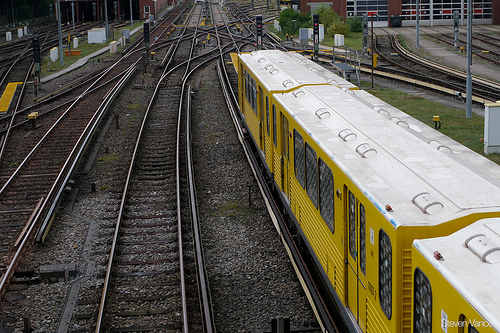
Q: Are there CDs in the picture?
A: No, there are no cds.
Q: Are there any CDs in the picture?
A: No, there are no cds.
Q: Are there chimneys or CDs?
A: No, there are no CDs or chimneys.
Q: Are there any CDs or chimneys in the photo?
A: No, there are no CDs or chimneys.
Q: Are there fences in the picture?
A: No, there are no fences.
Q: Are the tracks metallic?
A: Yes, the tracks are metallic.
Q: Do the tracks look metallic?
A: Yes, the tracks are metallic.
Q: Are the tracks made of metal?
A: Yes, the tracks are made of metal.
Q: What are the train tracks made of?
A: The train tracks are made of metal.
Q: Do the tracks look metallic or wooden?
A: The tracks are metallic.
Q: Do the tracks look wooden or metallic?
A: The tracks are metallic.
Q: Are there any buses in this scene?
A: No, there are no buses.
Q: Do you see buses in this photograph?
A: No, there are no buses.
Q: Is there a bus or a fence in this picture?
A: No, there are no buses or fences.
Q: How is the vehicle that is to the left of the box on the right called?
A: The vehicle is a car.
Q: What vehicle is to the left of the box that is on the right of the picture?
A: The vehicle is a car.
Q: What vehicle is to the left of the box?
A: The vehicle is a car.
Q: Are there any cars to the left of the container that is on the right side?
A: Yes, there is a car to the left of the box.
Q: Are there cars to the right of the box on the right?
A: No, the car is to the left of the box.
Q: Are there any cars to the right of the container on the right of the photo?
A: No, the car is to the left of the box.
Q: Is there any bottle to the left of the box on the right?
A: No, there is a car to the left of the box.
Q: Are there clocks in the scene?
A: No, there are no clocks.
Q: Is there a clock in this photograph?
A: No, there are no clocks.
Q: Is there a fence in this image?
A: No, there are no fences.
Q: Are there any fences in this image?
A: No, there are no fences.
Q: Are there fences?
A: No, there are no fences.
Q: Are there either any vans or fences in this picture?
A: No, there are no fences or vans.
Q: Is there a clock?
A: No, there are no clocks.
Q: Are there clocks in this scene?
A: No, there are no clocks.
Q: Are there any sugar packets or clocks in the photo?
A: No, there are no clocks or sugar packets.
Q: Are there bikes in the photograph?
A: No, there are no bikes.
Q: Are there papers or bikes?
A: No, there are no bikes or papers.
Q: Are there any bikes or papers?
A: No, there are no bikes or papers.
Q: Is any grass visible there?
A: Yes, there is grass.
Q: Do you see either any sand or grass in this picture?
A: Yes, there is grass.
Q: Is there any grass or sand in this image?
A: Yes, there is grass.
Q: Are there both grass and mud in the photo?
A: No, there is grass but no mud.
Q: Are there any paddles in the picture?
A: No, there are no paddles.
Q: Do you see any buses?
A: No, there are no buses.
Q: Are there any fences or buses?
A: No, there are no buses or fences.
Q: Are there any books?
A: No, there are no books.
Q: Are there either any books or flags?
A: No, there are no books or flags.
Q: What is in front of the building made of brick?
A: The shrub is in front of the building.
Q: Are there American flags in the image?
A: No, there are no American flags.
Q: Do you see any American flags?
A: No, there are no American flags.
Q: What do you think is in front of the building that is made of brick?
A: The shrub is in front of the building.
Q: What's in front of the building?
A: The shrub is in front of the building.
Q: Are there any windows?
A: Yes, there is a window.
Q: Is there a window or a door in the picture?
A: Yes, there is a window.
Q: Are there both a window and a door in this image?
A: Yes, there are both a window and a door.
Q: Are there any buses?
A: No, there are no buses.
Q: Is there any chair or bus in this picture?
A: No, there are no buses or chairs.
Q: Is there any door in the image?
A: Yes, there are doors.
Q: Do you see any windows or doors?
A: Yes, there are doors.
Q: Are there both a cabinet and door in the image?
A: No, there are doors but no cabinets.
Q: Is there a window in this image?
A: Yes, there is a window.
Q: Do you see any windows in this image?
A: Yes, there is a window.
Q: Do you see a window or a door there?
A: Yes, there is a window.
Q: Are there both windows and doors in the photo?
A: Yes, there are both a window and a door.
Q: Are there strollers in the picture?
A: No, there are no strollers.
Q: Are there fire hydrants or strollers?
A: No, there are no strollers or fire hydrants.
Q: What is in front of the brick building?
A: The shrub is in front of the building.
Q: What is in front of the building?
A: The shrub is in front of the building.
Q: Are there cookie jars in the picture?
A: No, there are no cookie jars.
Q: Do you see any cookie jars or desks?
A: No, there are no cookie jars or desks.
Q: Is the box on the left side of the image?
A: No, the box is on the right of the image.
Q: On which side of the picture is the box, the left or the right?
A: The box is on the right of the image.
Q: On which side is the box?
A: The box is on the right of the image.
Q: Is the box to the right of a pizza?
A: No, the box is to the right of the car.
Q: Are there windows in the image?
A: Yes, there are windows.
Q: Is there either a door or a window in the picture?
A: Yes, there are windows.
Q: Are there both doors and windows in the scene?
A: Yes, there are both windows and doors.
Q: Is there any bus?
A: No, there are no buses.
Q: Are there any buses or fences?
A: No, there are no buses or fences.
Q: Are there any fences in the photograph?
A: No, there are no fences.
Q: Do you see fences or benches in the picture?
A: No, there are no fences or benches.